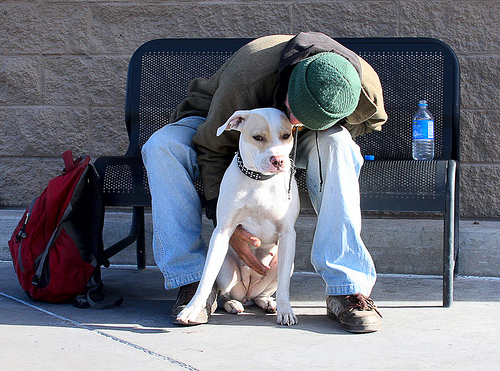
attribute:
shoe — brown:
[324, 294, 381, 334]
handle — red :
[61, 147, 79, 169]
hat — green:
[287, 52, 362, 134]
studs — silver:
[233, 151, 276, 185]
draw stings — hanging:
[288, 125, 321, 199]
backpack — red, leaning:
[3, 142, 121, 312]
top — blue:
[365, 151, 378, 163]